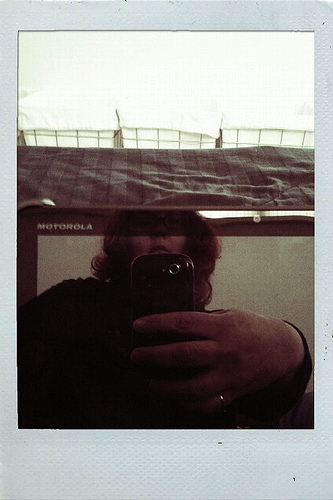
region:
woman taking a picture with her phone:
[37, 194, 292, 410]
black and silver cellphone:
[100, 237, 229, 366]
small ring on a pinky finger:
[117, 301, 249, 416]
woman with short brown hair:
[78, 183, 214, 329]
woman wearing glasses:
[99, 192, 208, 279]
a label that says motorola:
[24, 205, 110, 251]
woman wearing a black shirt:
[34, 264, 288, 414]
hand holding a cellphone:
[113, 254, 293, 408]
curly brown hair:
[87, 203, 137, 297]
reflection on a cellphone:
[25, 181, 280, 416]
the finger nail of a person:
[132, 315, 148, 332]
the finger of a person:
[130, 311, 228, 338]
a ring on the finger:
[215, 391, 229, 413]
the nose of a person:
[148, 215, 171, 242]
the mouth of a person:
[146, 240, 178, 255]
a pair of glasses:
[126, 210, 194, 234]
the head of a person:
[85, 207, 222, 306]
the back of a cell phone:
[129, 248, 199, 319]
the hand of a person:
[121, 306, 296, 423]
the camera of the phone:
[166, 258, 184, 278]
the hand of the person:
[126, 306, 292, 423]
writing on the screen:
[34, 219, 96, 233]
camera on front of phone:
[163, 261, 185, 276]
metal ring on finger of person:
[206, 383, 247, 417]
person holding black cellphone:
[108, 245, 227, 411]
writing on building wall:
[28, 217, 95, 236]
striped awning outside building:
[39, 143, 299, 206]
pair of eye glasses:
[121, 205, 194, 239]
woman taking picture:
[43, 201, 268, 408]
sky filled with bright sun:
[60, 34, 291, 117]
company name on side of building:
[33, 217, 96, 240]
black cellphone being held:
[127, 256, 197, 369]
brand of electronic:
[34, 220, 102, 233]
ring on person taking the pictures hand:
[215, 391, 230, 407]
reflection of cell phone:
[120, 245, 207, 382]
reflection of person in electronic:
[93, 211, 304, 417]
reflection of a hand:
[117, 298, 299, 417]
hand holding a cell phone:
[119, 240, 328, 418]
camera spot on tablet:
[250, 212, 263, 226]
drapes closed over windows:
[17, 45, 322, 135]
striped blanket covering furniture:
[20, 145, 312, 207]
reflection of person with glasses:
[95, 213, 224, 302]